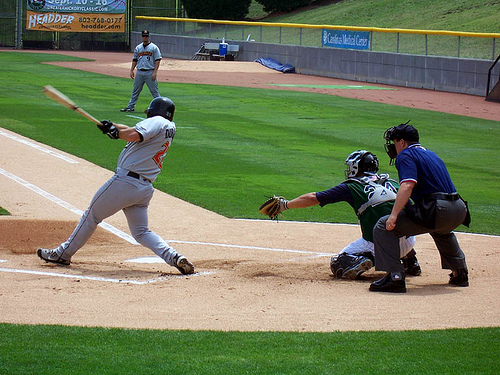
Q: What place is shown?
A: It is a field.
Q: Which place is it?
A: It is a field.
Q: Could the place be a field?
A: Yes, it is a field.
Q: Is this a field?
A: Yes, it is a field.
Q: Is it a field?
A: Yes, it is a field.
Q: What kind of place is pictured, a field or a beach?
A: It is a field.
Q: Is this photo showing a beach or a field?
A: It is showing a field.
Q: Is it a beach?
A: No, it is a field.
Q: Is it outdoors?
A: Yes, it is outdoors.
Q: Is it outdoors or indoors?
A: It is outdoors.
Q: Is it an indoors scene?
A: No, it is outdoors.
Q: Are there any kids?
A: No, there are no kids.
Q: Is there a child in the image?
A: No, there are no children.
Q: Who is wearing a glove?
A: The man is wearing a glove.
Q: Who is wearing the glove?
A: The man is wearing a glove.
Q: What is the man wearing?
A: The man is wearing a glove.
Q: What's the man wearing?
A: The man is wearing a glove.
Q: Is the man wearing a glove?
A: Yes, the man is wearing a glove.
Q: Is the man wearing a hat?
A: No, the man is wearing a glove.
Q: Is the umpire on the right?
A: Yes, the umpire is on the right of the image.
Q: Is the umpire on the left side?
A: No, the umpire is on the right of the image.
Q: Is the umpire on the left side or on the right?
A: The umpire is on the right of the image.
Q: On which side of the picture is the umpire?
A: The umpire is on the right of the image.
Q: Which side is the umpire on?
A: The umpire is on the right of the image.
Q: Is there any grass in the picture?
A: Yes, there is grass.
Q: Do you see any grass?
A: Yes, there is grass.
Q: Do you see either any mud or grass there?
A: Yes, there is grass.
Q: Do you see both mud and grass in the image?
A: No, there is grass but no mud.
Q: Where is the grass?
A: The grass is on the field.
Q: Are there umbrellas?
A: No, there are no umbrellas.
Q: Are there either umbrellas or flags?
A: No, there are no umbrellas or flags.